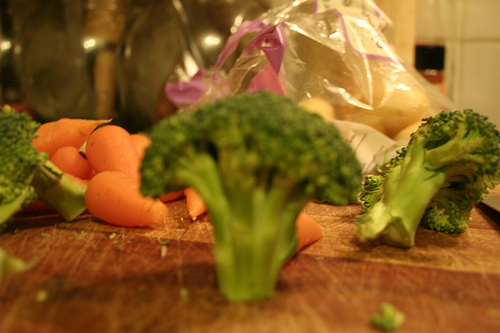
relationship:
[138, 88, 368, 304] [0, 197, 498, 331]
broccoli on table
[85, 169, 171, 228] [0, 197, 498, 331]
carrot on table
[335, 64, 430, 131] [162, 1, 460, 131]
potatoe in bag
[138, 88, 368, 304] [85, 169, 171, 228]
broccoli and carrot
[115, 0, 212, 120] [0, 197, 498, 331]
bowl on table